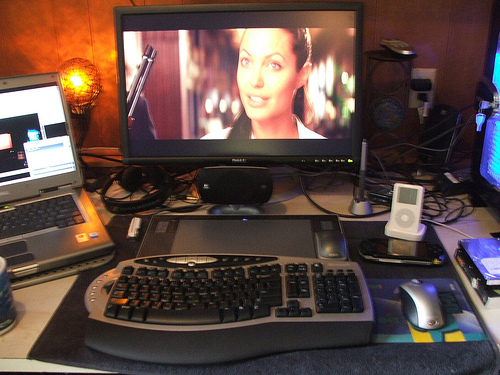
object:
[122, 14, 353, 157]
movie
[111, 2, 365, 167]
computer monitor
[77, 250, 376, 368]
computer keyboard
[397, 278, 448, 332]
wireless mouse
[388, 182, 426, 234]
ipod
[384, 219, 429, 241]
charger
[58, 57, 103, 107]
light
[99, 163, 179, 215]
headphones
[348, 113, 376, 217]
microphone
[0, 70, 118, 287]
laptop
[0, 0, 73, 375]
left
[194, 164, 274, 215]
speaker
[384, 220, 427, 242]
dock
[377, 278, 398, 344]
mouse pad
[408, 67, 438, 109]
outlet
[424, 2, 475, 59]
wall